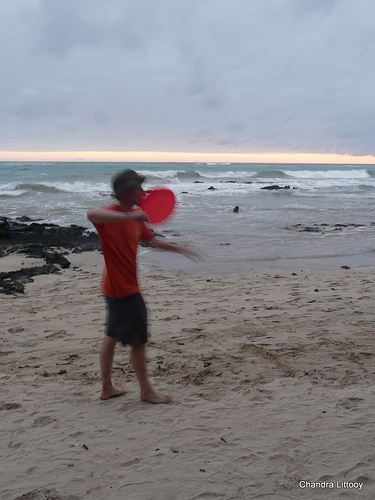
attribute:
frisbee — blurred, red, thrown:
[142, 187, 167, 223]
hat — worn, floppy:
[112, 166, 144, 187]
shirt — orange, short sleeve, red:
[101, 236, 137, 294]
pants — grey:
[111, 300, 149, 338]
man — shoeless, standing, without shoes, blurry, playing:
[77, 177, 176, 398]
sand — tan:
[218, 345, 276, 392]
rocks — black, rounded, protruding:
[20, 236, 52, 260]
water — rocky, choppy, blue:
[226, 184, 264, 202]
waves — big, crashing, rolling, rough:
[272, 194, 314, 219]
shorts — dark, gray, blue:
[105, 295, 143, 337]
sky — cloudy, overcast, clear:
[212, 62, 213, 63]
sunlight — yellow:
[144, 153, 154, 158]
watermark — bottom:
[297, 473, 365, 498]